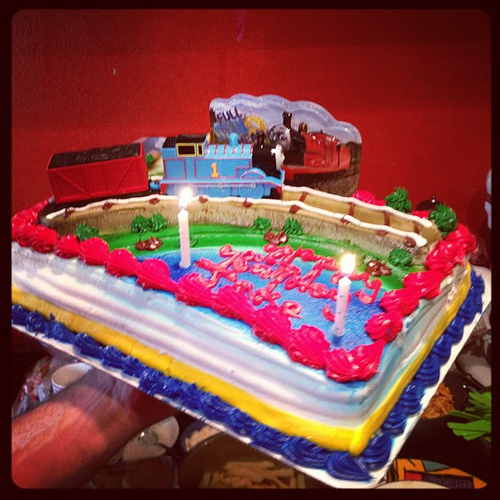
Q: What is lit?
A: Candles.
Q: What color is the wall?
A: Red.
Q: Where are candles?
A: On the cake.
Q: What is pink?
A: Frosting.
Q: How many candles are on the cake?
A: Two.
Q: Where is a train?
A: On the cake.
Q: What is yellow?
A: Frosting on cake.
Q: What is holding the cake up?
A: An arm.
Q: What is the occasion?
A: A birthday.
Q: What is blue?
A: Frosting.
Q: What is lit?
A: Two candles.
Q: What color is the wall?
A: Red.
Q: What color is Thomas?
A: Blue.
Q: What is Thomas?
A: A train.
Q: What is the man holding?
A: A cake.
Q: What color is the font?
A: Pink.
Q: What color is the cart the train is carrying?
A: Red.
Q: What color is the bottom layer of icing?
A: Blue.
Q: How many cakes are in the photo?
A: One.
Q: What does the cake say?
A: Happy Birthday Jake.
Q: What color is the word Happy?
A: Pink.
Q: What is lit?
A: Candles.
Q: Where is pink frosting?
A: On the cake.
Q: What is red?
A: Wall.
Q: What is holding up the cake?
A: An arm.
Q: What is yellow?
A: Frosting.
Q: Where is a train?
A: On the cake.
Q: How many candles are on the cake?
A: Two.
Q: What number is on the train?
A: 1.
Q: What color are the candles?
A: White.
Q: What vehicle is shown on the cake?
A: Train.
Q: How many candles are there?
A: 2.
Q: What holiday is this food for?
A: Birthday.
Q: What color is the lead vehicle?
A: Blue.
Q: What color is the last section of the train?
A: Red.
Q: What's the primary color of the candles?
A: White.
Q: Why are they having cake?
A: To celebrate a birthday.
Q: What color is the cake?
A: Pink and blue.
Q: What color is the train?
A: Blue.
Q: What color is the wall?
A: Red.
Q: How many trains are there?
A: Two.